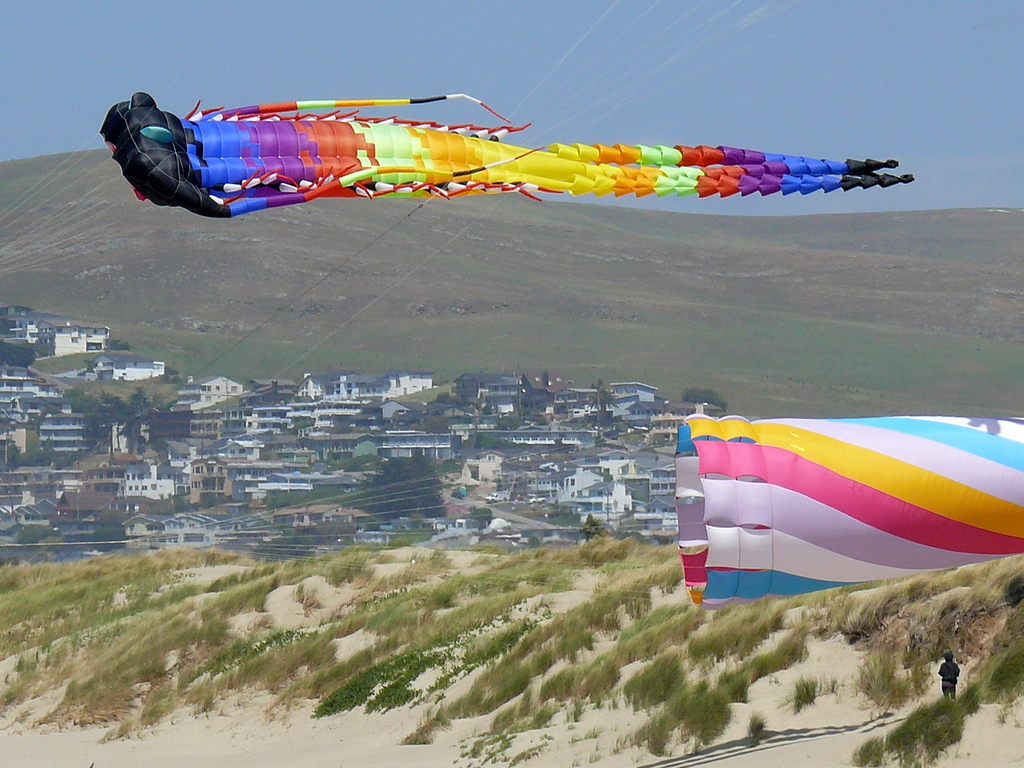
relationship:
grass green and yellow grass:
[0, 535, 1024, 768] [501, 591, 547, 663]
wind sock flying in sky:
[99, 92, 915, 218] [2, 1, 1022, 213]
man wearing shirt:
[937, 644, 963, 696] [941, 657, 963, 684]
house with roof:
[328, 364, 437, 395] [308, 366, 436, 380]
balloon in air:
[672, 409, 1022, 604] [4, 5, 1022, 764]